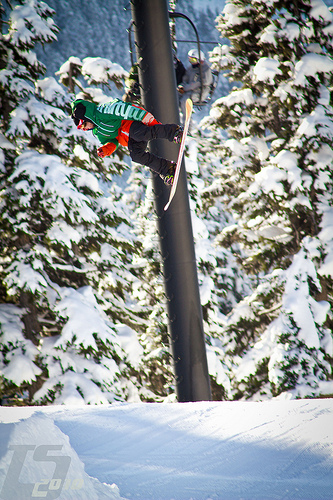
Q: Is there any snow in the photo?
A: Yes, there is snow.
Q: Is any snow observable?
A: Yes, there is snow.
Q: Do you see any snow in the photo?
A: Yes, there is snow.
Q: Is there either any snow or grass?
A: Yes, there is snow.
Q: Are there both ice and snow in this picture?
A: No, there is snow but no ice.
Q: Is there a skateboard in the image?
A: No, there are no skateboards.